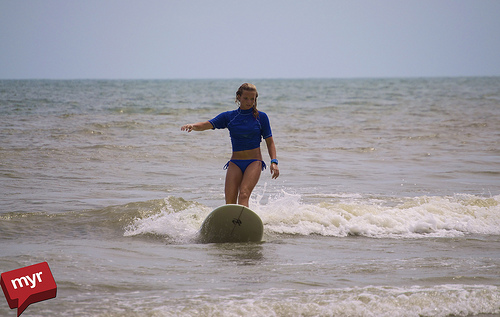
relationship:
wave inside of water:
[1, 194, 498, 244] [1, 78, 500, 315]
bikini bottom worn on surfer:
[220, 158, 267, 176] [180, 83, 281, 207]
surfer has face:
[180, 83, 281, 207] [238, 89, 258, 109]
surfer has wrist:
[180, 83, 281, 207] [267, 154, 280, 167]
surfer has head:
[180, 83, 281, 207] [233, 81, 261, 110]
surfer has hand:
[180, 83, 281, 207] [178, 124, 197, 136]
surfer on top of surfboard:
[180, 83, 281, 207] [198, 202, 265, 244]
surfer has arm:
[180, 83, 281, 207] [179, 110, 230, 133]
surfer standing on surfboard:
[180, 83, 281, 207] [198, 202, 265, 244]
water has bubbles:
[1, 78, 500, 315] [198, 279, 498, 315]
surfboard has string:
[198, 202, 265, 244] [229, 205, 247, 242]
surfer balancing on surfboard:
[180, 83, 281, 207] [198, 202, 265, 244]